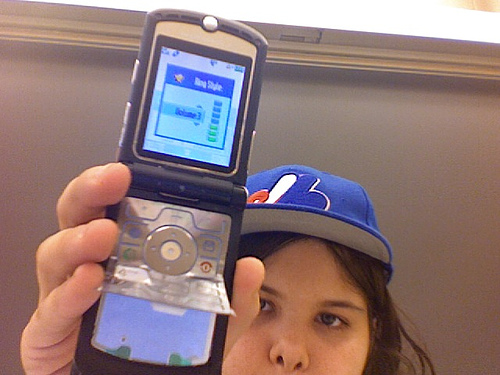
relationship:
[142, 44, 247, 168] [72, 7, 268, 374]
screen of phone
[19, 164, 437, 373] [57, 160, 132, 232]
person has finger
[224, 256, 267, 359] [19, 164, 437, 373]
thumb of person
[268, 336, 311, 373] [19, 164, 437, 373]
nose of person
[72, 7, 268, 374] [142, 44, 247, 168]
phone has screen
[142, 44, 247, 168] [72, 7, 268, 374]
screen on phone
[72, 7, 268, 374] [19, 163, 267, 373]
phone in hand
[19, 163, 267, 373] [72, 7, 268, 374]
hand holding phone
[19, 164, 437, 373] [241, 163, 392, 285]
person wearing hat